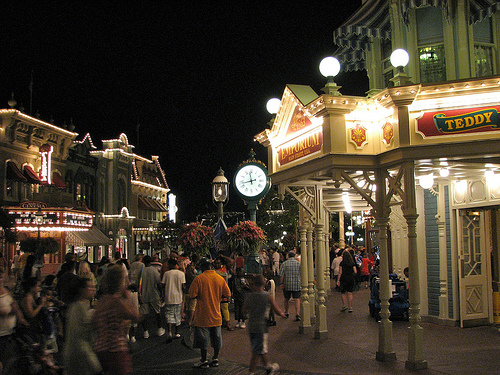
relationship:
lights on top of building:
[319, 41, 414, 73] [247, 2, 494, 329]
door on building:
[456, 206, 498, 326] [259, 0, 494, 368]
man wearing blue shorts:
[188, 257, 232, 368] [183, 309, 229, 355]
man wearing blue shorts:
[188, 257, 232, 368] [192, 326, 223, 350]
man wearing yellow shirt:
[188, 257, 232, 368] [188, 270, 231, 329]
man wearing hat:
[188, 257, 232, 368] [195, 249, 215, 264]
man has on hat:
[185, 252, 233, 371] [193, 254, 210, 265]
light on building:
[312, 57, 349, 84] [247, 2, 494, 329]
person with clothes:
[84, 248, 146, 371] [82, 259, 145, 374]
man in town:
[188, 257, 232, 368] [1, 4, 498, 332]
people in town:
[244, 274, 288, 374] [1, 4, 498, 332]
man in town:
[138, 256, 163, 338] [1, 4, 498, 332]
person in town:
[159, 256, 187, 338] [1, 4, 498, 332]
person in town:
[93, 265, 137, 371] [1, 4, 498, 332]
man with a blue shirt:
[137, 254, 164, 339] [276, 260, 301, 290]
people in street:
[27, 248, 237, 343] [129, 304, 388, 373]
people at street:
[191, 261, 293, 364] [284, 337, 341, 370]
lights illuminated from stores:
[275, 119, 323, 146] [253, 30, 498, 351]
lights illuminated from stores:
[355, 98, 395, 125] [253, 30, 498, 351]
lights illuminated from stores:
[414, 87, 493, 114] [253, 30, 498, 351]